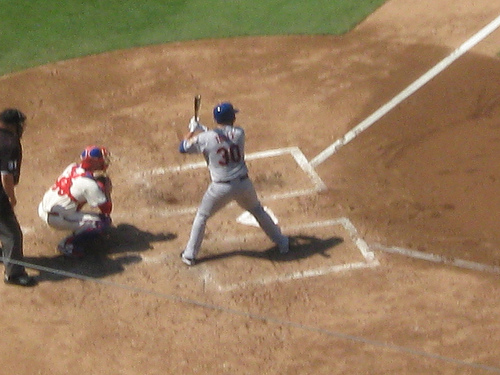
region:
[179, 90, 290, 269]
a baseball player batting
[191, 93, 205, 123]
the baseball bat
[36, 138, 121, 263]
the catcher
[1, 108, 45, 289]
the umpire watching the game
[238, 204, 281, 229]
the home plate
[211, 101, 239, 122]
the blue hat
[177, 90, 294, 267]
a man swinging a baseball bat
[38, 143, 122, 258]
a man crouched down waiting to catch the ball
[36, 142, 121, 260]
a man wearing a blue and red hat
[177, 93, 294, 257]
a man wearing white gloves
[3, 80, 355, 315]
man playing baseball on a field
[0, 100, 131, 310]
umpire behind catcher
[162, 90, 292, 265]
player 30 up at bat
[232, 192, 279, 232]
home plate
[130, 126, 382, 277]
powder on part of the batting area has rubbed away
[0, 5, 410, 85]
grass on the field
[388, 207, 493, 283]
first base line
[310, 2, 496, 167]
third base line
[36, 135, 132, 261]
catcher crouching down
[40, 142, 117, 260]
catcher wearing red and white uniform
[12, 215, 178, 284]
some shadows on the ground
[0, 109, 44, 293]
an umpire dressed in black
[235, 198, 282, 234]
the home plate on the ground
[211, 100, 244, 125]
a hard blue helmet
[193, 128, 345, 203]
chalk lines on the ground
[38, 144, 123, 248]
a red and white uniform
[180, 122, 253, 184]
a light grey jersey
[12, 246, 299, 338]
a thing grey cable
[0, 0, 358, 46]
some well trimmed grass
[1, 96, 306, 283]
a group of athletes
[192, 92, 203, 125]
baseball bat in a player's hand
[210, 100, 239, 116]
blue baseball hat on a player's head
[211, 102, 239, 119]
blue hat on a baseball player's head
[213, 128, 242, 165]
red print on the back of a baseball jersey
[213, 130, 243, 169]
name and number on the back of a jersey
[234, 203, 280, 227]
white base on a field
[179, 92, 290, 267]
baseball player preparing to swing his bat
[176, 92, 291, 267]
baseball player at bat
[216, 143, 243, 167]
red number 30 print on the back of a jersey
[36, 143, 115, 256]
baseball catcher on a field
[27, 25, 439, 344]
people playing in baseball game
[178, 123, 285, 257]
man wearing grey uniform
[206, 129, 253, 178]
red writing on uniform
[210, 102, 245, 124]
player wearing blue helmet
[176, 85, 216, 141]
player holding baseball bat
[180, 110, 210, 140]
player wearing white gloves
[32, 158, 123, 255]
player squatting in dirt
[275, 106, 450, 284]
white lines drawn in dirt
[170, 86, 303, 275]
player standing next to base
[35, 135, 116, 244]
man wearing white uniform